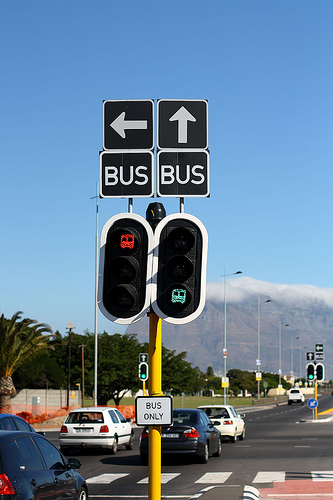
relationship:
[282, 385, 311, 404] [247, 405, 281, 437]
white jeep on road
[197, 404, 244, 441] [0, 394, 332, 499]
car on highway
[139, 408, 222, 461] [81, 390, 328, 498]
car on highway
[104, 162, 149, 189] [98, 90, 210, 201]
bus on sign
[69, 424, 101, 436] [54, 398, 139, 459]
plate on car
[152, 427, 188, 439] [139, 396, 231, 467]
plate on car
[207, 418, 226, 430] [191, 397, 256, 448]
plate on car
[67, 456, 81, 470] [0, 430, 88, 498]
mirror on car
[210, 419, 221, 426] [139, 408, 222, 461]
mirror on car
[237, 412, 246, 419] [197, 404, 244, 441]
mirror on car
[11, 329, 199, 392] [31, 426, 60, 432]
tree near curb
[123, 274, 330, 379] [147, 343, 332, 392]
mountain on horizon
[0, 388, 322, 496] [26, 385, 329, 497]
vehicles driving on street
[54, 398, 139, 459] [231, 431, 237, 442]
car has tire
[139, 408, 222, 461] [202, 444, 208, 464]
car has tire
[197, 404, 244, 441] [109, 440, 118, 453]
car has tire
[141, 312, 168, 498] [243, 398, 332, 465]
post by road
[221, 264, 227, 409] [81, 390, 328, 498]
post by highway